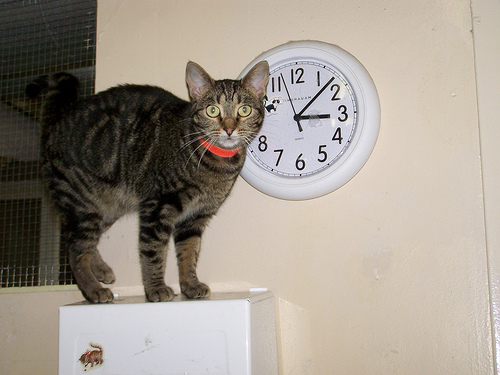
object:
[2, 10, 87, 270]
metal grate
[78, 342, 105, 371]
mouse image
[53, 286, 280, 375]
metal box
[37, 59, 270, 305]
cat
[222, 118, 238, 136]
nose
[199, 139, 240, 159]
red collar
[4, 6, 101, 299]
screen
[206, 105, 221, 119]
eye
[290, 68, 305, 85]
number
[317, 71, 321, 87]
number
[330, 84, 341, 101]
number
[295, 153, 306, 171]
number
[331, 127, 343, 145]
number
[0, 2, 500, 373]
wall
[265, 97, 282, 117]
dog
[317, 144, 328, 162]
number five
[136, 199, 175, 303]
leg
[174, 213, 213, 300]
leg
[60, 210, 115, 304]
leg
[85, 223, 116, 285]
leg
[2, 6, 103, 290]
opening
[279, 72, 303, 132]
hands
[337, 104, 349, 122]
three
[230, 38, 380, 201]
clock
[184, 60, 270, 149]
head